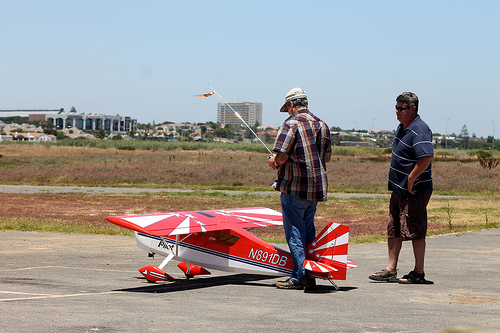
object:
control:
[186, 78, 335, 290]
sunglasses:
[397, 104, 412, 111]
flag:
[185, 88, 215, 102]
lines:
[0, 285, 119, 303]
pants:
[384, 182, 435, 241]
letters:
[247, 248, 261, 261]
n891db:
[247, 245, 291, 270]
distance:
[121, 101, 275, 135]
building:
[23, 111, 142, 133]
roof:
[17, 130, 67, 140]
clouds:
[25, 51, 56, 81]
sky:
[0, 0, 500, 140]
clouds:
[332, 100, 370, 118]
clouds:
[72, 59, 129, 93]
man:
[367, 91, 438, 284]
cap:
[278, 87, 312, 113]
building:
[211, 101, 266, 136]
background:
[0, 0, 500, 332]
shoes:
[394, 269, 428, 284]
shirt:
[386, 118, 437, 195]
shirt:
[269, 106, 333, 204]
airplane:
[103, 204, 360, 287]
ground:
[0, 136, 500, 332]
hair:
[394, 91, 423, 110]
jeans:
[278, 191, 323, 283]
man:
[266, 86, 332, 291]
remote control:
[265, 154, 277, 167]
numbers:
[261, 250, 270, 262]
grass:
[441, 202, 458, 232]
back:
[47, 112, 140, 137]